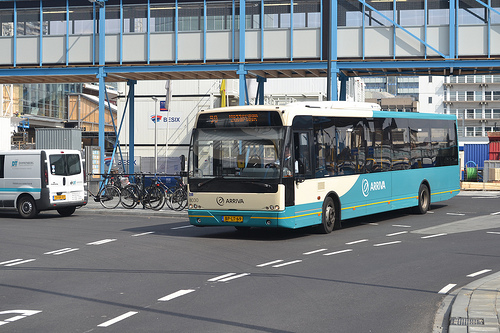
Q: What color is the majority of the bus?
A: Blue.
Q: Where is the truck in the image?
A: On the left.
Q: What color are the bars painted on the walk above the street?
A: Blue.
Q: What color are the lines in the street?
A: White.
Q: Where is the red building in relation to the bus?
A: Behind it.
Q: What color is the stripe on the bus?
A: Yellow.